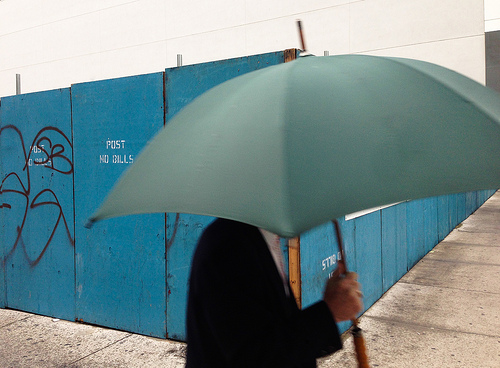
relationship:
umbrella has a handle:
[87, 55, 498, 241] [351, 329, 373, 368]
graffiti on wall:
[1, 117, 79, 264] [1, 87, 78, 322]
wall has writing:
[1, 87, 78, 322] [29, 143, 54, 168]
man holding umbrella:
[183, 218, 360, 367] [87, 55, 498, 241]